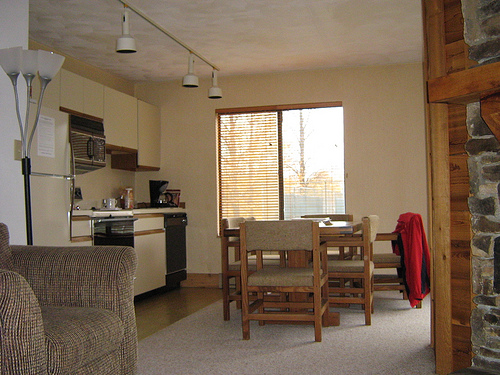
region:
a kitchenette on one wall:
[21, 47, 191, 302]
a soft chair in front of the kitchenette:
[0, 216, 151, 373]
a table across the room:
[212, 212, 400, 342]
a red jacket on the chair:
[390, 210, 434, 305]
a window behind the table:
[207, 104, 349, 241]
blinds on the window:
[222, 110, 336, 218]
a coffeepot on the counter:
[144, 177, 171, 204]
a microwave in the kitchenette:
[66, 116, 106, 167]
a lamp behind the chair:
[0, 39, 63, 251]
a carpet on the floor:
[135, 284, 433, 372]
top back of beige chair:
[241, 222, 322, 244]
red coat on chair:
[412, 224, 419, 263]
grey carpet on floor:
[208, 343, 254, 373]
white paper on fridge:
[33, 113, 63, 161]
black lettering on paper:
[40, 134, 56, 152]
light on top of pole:
[2, 46, 65, 83]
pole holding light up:
[19, 146, 41, 248]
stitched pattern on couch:
[54, 285, 97, 321]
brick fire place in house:
[476, 149, 492, 250]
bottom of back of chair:
[229, 309, 336, 356]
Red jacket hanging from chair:
[389, 209, 435, 311]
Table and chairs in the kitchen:
[219, 208, 423, 346]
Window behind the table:
[214, 99, 346, 239]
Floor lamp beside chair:
[0, 40, 65, 245]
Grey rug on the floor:
[140, 282, 430, 369]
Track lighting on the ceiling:
[106, 1, 222, 96]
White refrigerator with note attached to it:
[20, 101, 70, 231]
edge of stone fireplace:
[462, 0, 494, 371]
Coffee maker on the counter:
[145, 175, 171, 205]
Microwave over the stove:
[71, 115, 108, 167]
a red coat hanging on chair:
[394, 211, 432, 309]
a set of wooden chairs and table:
[219, 211, 421, 343]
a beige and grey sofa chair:
[0, 223, 140, 373]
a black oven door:
[91, 211, 135, 250]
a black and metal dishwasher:
[164, 208, 189, 285]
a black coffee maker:
[147, 176, 169, 209]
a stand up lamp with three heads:
[2, 44, 64, 245]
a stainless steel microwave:
[69, 122, 101, 173]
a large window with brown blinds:
[216, 105, 343, 239]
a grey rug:
[136, 286, 433, 373]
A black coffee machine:
[146, 178, 177, 206]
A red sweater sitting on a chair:
[391, 201, 432, 302]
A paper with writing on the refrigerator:
[35, 110, 56, 155]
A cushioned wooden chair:
[236, 215, 336, 335]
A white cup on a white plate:
[100, 195, 117, 210]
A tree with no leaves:
[290, 110, 320, 185]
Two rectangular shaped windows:
[215, 110, 340, 215]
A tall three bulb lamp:
[0, 42, 75, 232]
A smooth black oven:
[91, 215, 131, 245]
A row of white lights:
[115, 5, 230, 101]